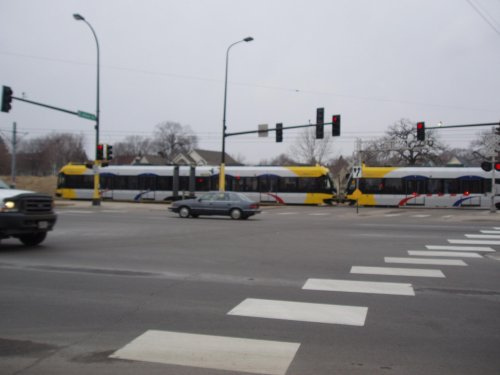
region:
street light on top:
[213, 19, 265, 56]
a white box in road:
[209, 247, 404, 360]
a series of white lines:
[79, 238, 495, 355]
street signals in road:
[223, 93, 385, 164]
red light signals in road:
[311, 93, 350, 132]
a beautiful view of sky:
[20, 9, 480, 136]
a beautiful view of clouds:
[33, 3, 495, 155]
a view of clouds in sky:
[26, 7, 496, 172]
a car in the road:
[154, 180, 275, 225]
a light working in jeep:
[0, 180, 29, 244]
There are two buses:
[45, 156, 491, 201]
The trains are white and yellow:
[53, 158, 486, 207]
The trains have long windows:
[63, 176, 498, 189]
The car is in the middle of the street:
[165, 185, 276, 232]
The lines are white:
[232, 295, 367, 332]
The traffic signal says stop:
[411, 110, 433, 148]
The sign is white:
[350, 163, 361, 183]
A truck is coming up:
[0, 173, 75, 273]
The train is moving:
[48, 155, 486, 205]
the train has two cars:
[57, 150, 497, 205]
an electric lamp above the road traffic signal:
[219, 30, 352, 210]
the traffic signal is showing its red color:
[218, 99, 353, 214]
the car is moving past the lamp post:
[145, 26, 262, 226]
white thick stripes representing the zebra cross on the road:
[106, 215, 497, 372]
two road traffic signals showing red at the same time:
[217, 100, 499, 218]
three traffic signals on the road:
[1, 81, 494, 243]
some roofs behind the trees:
[114, 111, 244, 165]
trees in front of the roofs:
[114, 118, 239, 163]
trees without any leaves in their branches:
[113, 128, 207, 162]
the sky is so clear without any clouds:
[0, 9, 487, 129]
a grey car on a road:
[166, 189, 263, 229]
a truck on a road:
[0, 177, 57, 253]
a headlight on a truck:
[3, 196, 16, 210]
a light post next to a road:
[73, 12, 110, 205]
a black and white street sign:
[348, 164, 363, 181]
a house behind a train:
[141, 146, 234, 166]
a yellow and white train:
[52, 157, 499, 209]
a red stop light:
[95, 142, 104, 164]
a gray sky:
[1, 2, 498, 163]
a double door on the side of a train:
[402, 173, 425, 210]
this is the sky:
[313, 14, 437, 76]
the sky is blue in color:
[290, 32, 365, 64]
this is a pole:
[86, 20, 112, 168]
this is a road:
[274, 214, 404, 344]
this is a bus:
[366, 166, 439, 197]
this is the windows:
[383, 178, 417, 192]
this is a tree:
[153, 128, 195, 157]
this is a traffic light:
[399, 117, 430, 145]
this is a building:
[183, 136, 236, 177]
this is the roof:
[191, 148, 222, 160]